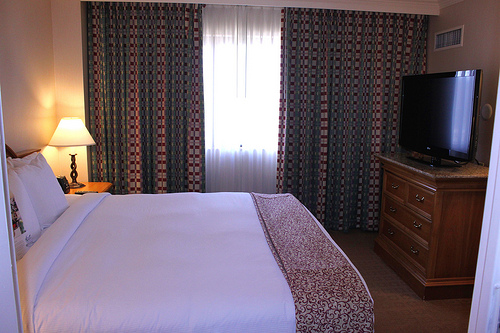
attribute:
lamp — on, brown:
[44, 114, 99, 160]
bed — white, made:
[70, 190, 334, 312]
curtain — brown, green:
[315, 30, 365, 91]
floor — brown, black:
[364, 259, 399, 307]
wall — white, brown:
[16, 20, 65, 65]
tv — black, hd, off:
[404, 71, 488, 154]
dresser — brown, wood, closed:
[385, 162, 445, 254]